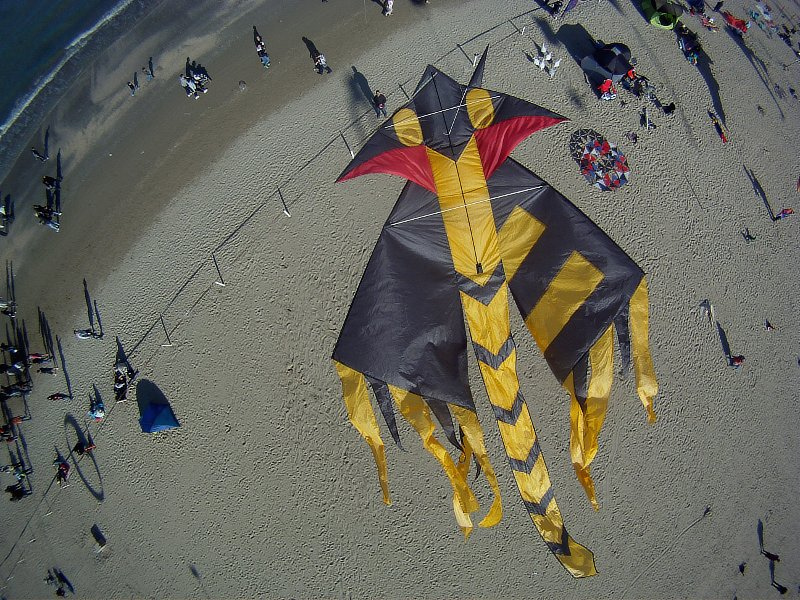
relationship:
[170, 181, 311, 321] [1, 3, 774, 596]
poles in sand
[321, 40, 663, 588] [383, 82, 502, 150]
kite has eyes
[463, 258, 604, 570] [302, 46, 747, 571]
stripes on kite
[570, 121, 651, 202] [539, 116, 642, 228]
umbrellas below kite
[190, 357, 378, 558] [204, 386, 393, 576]
sand on beach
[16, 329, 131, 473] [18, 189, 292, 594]
people on beach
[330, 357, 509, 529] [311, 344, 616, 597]
streamers on kite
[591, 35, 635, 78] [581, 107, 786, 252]
umbrella in sand